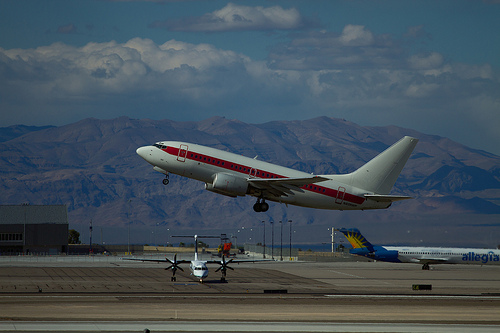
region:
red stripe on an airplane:
[160, 139, 365, 208]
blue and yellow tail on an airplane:
[342, 220, 375, 262]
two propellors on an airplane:
[160, 252, 240, 282]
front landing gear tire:
[157, 166, 172, 186]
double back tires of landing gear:
[248, 194, 273, 214]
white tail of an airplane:
[347, 97, 417, 194]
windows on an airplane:
[168, 145, 232, 170]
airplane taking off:
[135, 125, 440, 233]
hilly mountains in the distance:
[50, 101, 118, 167]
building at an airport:
[9, 186, 86, 272]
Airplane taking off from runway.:
[131, 133, 429, 215]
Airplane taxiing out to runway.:
[116, 230, 278, 285]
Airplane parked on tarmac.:
[334, 223, 499, 275]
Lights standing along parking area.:
[254, 215, 306, 261]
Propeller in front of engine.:
[158, 251, 185, 277]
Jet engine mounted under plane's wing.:
[207, 170, 255, 200]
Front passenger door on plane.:
[173, 142, 193, 164]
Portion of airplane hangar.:
[3, 195, 80, 260]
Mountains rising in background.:
[48, 108, 365, 226]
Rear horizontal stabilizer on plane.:
[360, 185, 415, 205]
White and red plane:
[130, 111, 433, 225]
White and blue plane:
[333, 214, 499, 286]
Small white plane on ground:
[118, 224, 283, 294]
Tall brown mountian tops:
[17, 96, 417, 136]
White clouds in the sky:
[59, 16, 84, 43]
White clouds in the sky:
[151, 14, 198, 52]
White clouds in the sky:
[218, 6, 295, 41]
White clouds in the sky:
[318, 19, 379, 54]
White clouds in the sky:
[399, 43, 472, 106]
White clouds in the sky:
[23, 22, 480, 108]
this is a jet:
[139, 134, 369, 226]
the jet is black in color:
[367, 165, 404, 193]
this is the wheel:
[249, 200, 267, 212]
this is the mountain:
[251, 126, 319, 154]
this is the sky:
[137, 15, 358, 97]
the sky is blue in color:
[438, 13, 495, 75]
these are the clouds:
[131, 42, 211, 76]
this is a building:
[17, 202, 61, 244]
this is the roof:
[28, 212, 77, 230]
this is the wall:
[32, 233, 72, 251]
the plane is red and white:
[121, 124, 426, 229]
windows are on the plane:
[183, 140, 265, 177]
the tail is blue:
[336, 223, 398, 285]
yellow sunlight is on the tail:
[348, 225, 363, 254]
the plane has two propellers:
[116, 218, 293, 331]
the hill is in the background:
[48, 82, 405, 137]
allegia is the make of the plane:
[456, 244, 498, 269]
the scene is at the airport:
[6, 54, 496, 331]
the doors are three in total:
[164, 118, 350, 216]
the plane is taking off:
[122, 102, 450, 227]